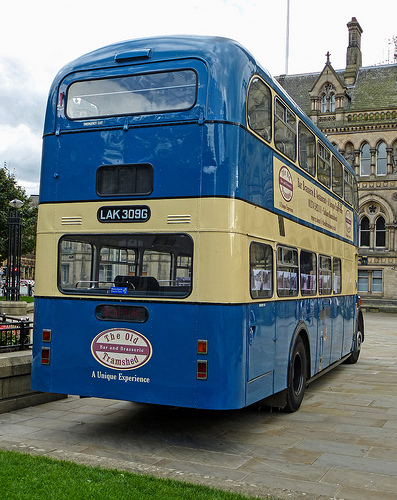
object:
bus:
[27, 32, 365, 409]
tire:
[287, 334, 313, 414]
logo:
[89, 325, 153, 372]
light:
[39, 325, 54, 346]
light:
[194, 336, 210, 357]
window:
[64, 66, 200, 122]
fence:
[0, 311, 34, 356]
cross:
[323, 50, 334, 64]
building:
[269, 12, 396, 317]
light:
[6, 195, 27, 212]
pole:
[10, 209, 18, 303]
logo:
[279, 160, 295, 205]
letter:
[97, 208, 108, 222]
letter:
[100, 206, 123, 222]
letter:
[111, 207, 122, 223]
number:
[119, 208, 129, 221]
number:
[126, 208, 137, 222]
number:
[132, 206, 142, 222]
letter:
[140, 207, 151, 223]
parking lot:
[1, 307, 396, 497]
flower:
[0, 321, 12, 335]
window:
[243, 69, 275, 151]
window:
[273, 86, 299, 167]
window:
[295, 113, 318, 184]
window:
[315, 134, 333, 196]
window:
[330, 147, 344, 202]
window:
[355, 134, 374, 179]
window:
[373, 136, 389, 178]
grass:
[0, 447, 253, 499]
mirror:
[358, 252, 370, 269]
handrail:
[64, 80, 200, 101]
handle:
[56, 89, 66, 110]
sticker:
[107, 284, 130, 296]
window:
[55, 230, 196, 301]